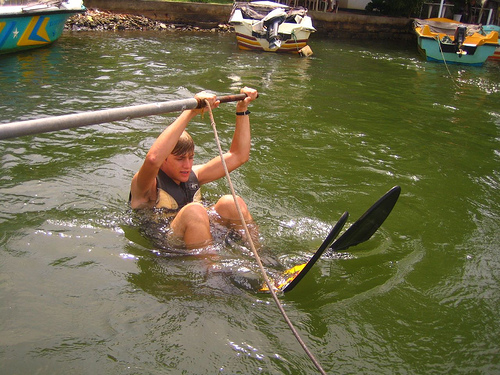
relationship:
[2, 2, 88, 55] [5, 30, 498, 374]
boat in water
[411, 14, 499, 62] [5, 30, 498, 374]
boat in water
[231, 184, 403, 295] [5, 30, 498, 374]
skis in water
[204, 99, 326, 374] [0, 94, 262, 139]
rope attached to ski pole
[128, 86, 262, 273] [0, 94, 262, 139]
man holding onto ski pole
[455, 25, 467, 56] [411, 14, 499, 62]
motor on a boat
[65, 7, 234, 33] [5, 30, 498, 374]
debri next to water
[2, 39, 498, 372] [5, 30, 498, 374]
ripples in water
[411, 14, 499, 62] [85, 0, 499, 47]
boat at dock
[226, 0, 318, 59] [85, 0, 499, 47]
boat at dock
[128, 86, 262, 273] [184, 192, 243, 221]
man has knees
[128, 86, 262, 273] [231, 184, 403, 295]
man wearing skis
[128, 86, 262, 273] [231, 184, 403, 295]
man on skis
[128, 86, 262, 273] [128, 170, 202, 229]
man wearing life vest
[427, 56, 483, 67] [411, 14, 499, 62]
stripe on boat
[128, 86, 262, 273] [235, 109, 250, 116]
man wearing a watch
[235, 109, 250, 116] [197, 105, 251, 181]
watch on left arm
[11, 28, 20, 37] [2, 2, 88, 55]
star on boat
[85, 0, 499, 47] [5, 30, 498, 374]
dock by water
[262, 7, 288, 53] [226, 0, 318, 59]
motor on boat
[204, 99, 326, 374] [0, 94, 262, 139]
rope on ski pole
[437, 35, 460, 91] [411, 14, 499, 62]
rope on boat